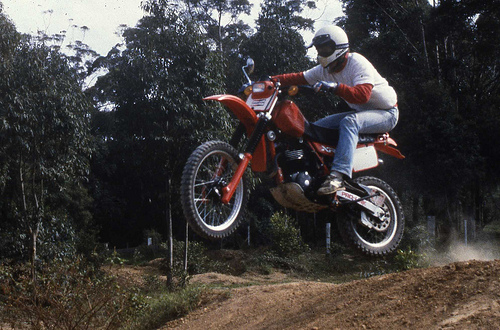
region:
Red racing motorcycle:
[175, 60, 410, 262]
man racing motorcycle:
[178, 17, 425, 264]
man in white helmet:
[185, 22, 424, 259]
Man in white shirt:
[287, 12, 403, 159]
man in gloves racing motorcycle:
[233, 19, 418, 168]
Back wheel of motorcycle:
[335, 168, 415, 268]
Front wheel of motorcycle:
[170, 133, 267, 248]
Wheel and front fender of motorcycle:
[178, 85, 283, 257]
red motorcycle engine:
[244, 83, 335, 237]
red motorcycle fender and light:
[201, 55, 292, 137]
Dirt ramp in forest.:
[160, 258, 499, 323]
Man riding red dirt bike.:
[181, 24, 423, 256]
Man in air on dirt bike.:
[174, 24, 409, 254]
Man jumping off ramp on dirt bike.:
[180, 24, 425, 265]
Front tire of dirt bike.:
[180, 134, 250, 246]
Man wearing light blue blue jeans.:
[307, 22, 403, 181]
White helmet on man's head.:
[307, 22, 349, 68]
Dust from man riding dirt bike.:
[413, 223, 495, 272]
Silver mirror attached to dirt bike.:
[232, 55, 257, 85]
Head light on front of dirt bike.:
[250, 74, 266, 99]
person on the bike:
[273, 33, 401, 163]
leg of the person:
[308, 107, 382, 213]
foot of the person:
[312, 163, 356, 202]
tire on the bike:
[166, 130, 266, 235]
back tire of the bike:
[321, 169, 414, 262]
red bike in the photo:
[179, 95, 426, 245]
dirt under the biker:
[301, 274, 379, 321]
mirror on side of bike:
[215, 50, 270, 100]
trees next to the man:
[36, 83, 175, 217]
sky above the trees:
[70, 4, 137, 67]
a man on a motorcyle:
[171, 18, 404, 260]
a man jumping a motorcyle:
[182, 24, 421, 269]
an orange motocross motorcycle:
[164, 10, 418, 260]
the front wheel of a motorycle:
[172, 138, 251, 242]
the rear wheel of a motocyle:
[330, 175, 412, 256]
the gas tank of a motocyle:
[273, 92, 315, 144]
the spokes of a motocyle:
[202, 159, 219, 219]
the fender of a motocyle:
[198, 85, 256, 132]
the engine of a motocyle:
[270, 140, 317, 195]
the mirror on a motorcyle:
[239, 51, 256, 71]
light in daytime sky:
[2, 1, 349, 78]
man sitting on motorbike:
[180, 25, 410, 255]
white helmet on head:
[313, 25, 349, 69]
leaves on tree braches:
[3, 45, 90, 267]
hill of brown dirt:
[209, 260, 499, 328]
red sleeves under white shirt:
[273, 51, 397, 103]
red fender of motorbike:
[208, 92, 267, 172]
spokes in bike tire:
[196, 157, 237, 221]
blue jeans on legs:
[316, 107, 399, 176]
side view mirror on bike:
[241, 57, 258, 86]